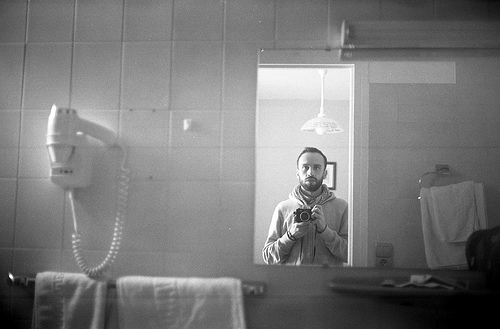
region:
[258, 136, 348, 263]
huppster [yuppie who somehow believes self 'hip'] pretending taking a black+white photo of himself w/ a camera & not a telephone makes him look 'deep'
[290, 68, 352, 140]
hanging lamp above yuppie's head, but which probably wont fall on it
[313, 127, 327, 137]
big white lightbulb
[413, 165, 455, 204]
towel ring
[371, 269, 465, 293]
a tip for the hotel maid?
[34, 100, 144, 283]
weird little blowdryer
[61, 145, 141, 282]
blowdryer cord just beginning to unravel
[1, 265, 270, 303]
metal towel bar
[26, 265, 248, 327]
bath towel+hand towel, both light colour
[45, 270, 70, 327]
greek key design on hand towel but not on bath towel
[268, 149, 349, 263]
A reflection in the mirror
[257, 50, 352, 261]
A mirror on the wall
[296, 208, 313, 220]
A camera in the man's hands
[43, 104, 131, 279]
A blow dryer by the mirror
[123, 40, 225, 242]
The wall has rectangular tiles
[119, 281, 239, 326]
A towel on a rack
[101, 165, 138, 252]
The cord to the blow dryer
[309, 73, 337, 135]
A lamp in the mirror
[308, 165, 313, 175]
The reflected nose of the man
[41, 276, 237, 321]
Two white towels on the rack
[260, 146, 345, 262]
A man taking a picture in the mirror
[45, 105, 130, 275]
Blow dryer attached to the wall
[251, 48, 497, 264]
A mirror on the wall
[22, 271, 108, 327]
Folded towel hanging from the towel rack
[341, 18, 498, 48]
Long light bulb above the mirror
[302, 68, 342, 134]
Ceiling lamp above the man's head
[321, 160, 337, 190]
Picture frame on the wall behind the man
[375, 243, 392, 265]
Two buttons on a light switch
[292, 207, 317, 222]
Camera in the man's hands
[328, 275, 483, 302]
Shelf under the mirror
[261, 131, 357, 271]
This is a person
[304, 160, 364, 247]
This is a person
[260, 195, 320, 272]
This is a person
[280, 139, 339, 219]
This is a person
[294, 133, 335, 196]
Head of a person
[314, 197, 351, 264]
Hand of a person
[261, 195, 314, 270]
Hand of a person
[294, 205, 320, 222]
This is a camera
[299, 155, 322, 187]
Face of a person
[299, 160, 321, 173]
Eyes of a person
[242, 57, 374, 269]
a man taking a selfie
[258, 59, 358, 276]
a man taking a selfie with a camera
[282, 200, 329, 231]
a digital camera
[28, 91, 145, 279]
a white hair dryer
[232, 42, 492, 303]
a mirror in a bathroom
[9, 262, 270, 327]
a towel rack with white towels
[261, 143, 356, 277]
a white male wearing a hoodie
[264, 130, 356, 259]
a guy standing in a bathroom doorway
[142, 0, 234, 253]
a tiled bathroom wall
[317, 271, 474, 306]
a small shelf in a bathroom holding a toothbrush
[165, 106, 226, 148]
A tile in a wall.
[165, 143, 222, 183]
A tile in a wall.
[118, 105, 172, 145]
A tile in a wall.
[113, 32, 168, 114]
A tile in a wall.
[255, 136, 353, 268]
A man holding a camera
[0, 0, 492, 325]
White tiles on the wall